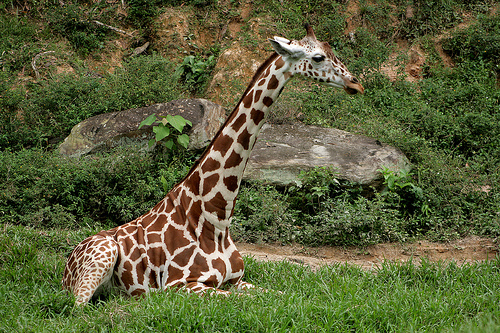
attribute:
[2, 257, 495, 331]
grass — green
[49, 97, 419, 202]
barren rock — large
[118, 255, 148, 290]
spots — brown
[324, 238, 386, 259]
dirt — brown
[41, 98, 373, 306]
giraffe — sitting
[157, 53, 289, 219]
neck — long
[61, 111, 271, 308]
giraffe — brown and white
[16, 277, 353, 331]
grass — green, tall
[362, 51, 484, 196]
bush — large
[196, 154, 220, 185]
spot — brown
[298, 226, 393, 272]
ground — barren